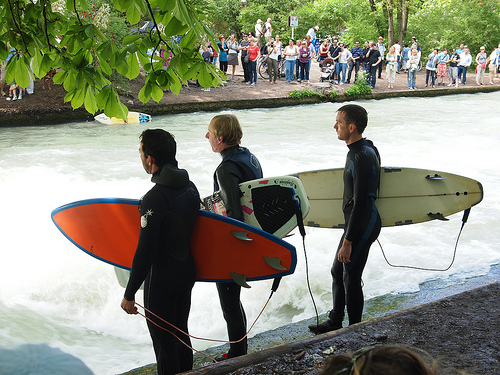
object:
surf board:
[94, 111, 153, 126]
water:
[3, 90, 471, 296]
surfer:
[308, 101, 387, 335]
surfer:
[203, 111, 273, 363]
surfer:
[128, 127, 202, 375]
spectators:
[330, 38, 342, 83]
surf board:
[49, 197, 299, 287]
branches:
[5, 1, 35, 62]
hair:
[318, 344, 432, 374]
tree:
[370, 0, 415, 75]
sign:
[288, 16, 299, 27]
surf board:
[286, 164, 485, 230]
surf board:
[197, 173, 311, 243]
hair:
[138, 127, 178, 166]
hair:
[212, 114, 243, 146]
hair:
[335, 103, 369, 135]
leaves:
[104, 87, 121, 122]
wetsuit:
[329, 141, 381, 324]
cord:
[378, 214, 473, 273]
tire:
[258, 60, 271, 80]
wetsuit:
[212, 146, 261, 337]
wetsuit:
[122, 171, 203, 372]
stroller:
[318, 59, 336, 83]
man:
[362, 43, 383, 89]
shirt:
[365, 50, 380, 65]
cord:
[295, 213, 321, 336]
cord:
[134, 286, 282, 363]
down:
[0, 330, 495, 375]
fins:
[229, 271, 252, 290]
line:
[309, 193, 454, 204]